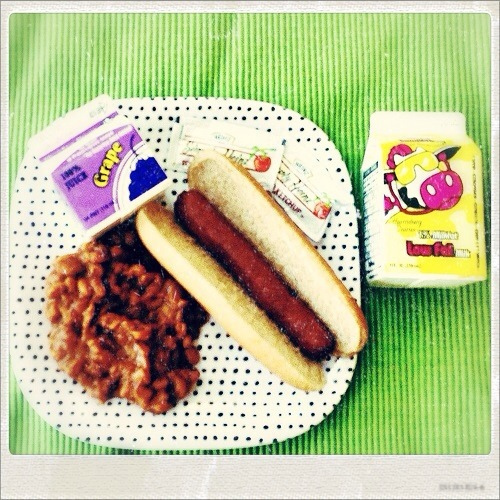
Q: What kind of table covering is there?
A: A tablecloth.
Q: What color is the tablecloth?
A: Green.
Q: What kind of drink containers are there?
A: A carton.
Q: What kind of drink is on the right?
A: Milk.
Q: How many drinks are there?
A: Two.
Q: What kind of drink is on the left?
A: Grape juice.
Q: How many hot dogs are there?
A: One.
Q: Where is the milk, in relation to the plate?
A: On the right.